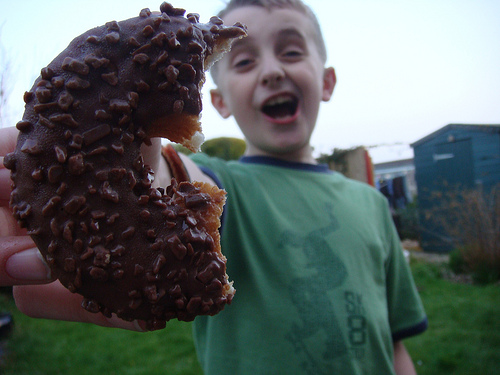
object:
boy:
[0, 0, 433, 375]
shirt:
[178, 154, 430, 375]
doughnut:
[0, 1, 248, 333]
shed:
[406, 120, 499, 253]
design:
[270, 199, 347, 374]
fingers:
[10, 279, 151, 333]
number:
[344, 314, 367, 349]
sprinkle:
[129, 52, 151, 67]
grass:
[394, 255, 499, 374]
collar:
[236, 155, 329, 173]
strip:
[202, 179, 226, 237]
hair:
[206, 0, 328, 85]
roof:
[406, 122, 499, 148]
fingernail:
[6, 246, 52, 285]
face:
[210, 7, 325, 154]